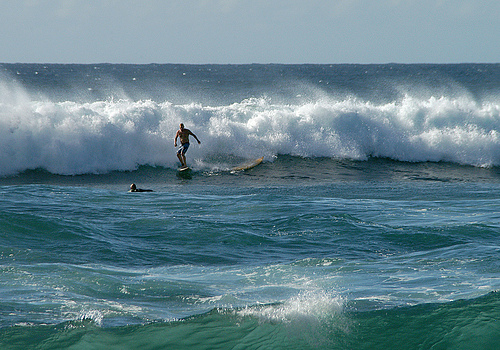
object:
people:
[125, 178, 156, 202]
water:
[0, 64, 500, 350]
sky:
[3, 3, 500, 64]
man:
[167, 122, 205, 169]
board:
[172, 163, 194, 176]